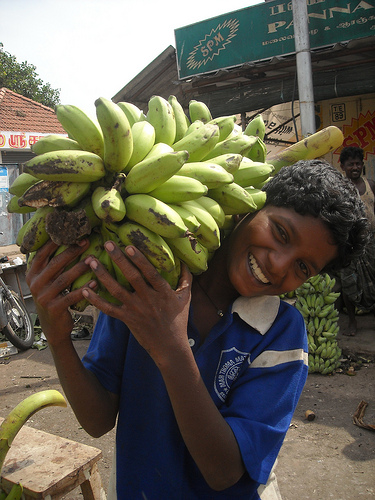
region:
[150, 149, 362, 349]
a boy is smiling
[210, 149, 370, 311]
boy has black curly hair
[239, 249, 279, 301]
teeth of boy are white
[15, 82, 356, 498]
boy carry a handles of bananas on right shoulder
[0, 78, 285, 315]
bananas are green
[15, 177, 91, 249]
two bananas are damaged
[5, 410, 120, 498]
a wood bench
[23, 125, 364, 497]
boy wears a blue short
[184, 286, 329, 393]
collar of blue short is white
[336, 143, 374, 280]
a woman wears a tank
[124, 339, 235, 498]
A boy in blue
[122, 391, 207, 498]
A boy in blue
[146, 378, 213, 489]
A boy in blue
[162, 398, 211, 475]
A boy in blue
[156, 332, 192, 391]
A boy in blue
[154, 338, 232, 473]
A boy in blue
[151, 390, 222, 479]
A boy in blue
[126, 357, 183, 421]
A boy in blue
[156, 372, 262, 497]
A boy in blue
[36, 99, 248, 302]
large bunch of green bananas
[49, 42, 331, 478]
boy holding bunch of bananas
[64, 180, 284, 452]
boy wearing blue sports shirt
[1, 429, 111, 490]
pale brown wooden stool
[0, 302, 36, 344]
tire of a motorbike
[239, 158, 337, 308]
man's smiling face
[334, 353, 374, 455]
trash on the ground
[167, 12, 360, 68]
green store sign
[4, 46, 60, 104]
dark green tree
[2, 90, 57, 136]
roof with red tiles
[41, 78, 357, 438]
boy carrying green bananas on his shoulder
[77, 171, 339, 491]
boy in a blue and white polo shirt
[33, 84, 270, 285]
large bunch of green bananas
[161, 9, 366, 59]
green building sign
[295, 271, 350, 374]
bunch of green bananas on the ground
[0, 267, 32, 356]
motorcycle tire in the background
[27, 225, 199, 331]
hands of a boy carrying bananas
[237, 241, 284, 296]
smile on a boy's face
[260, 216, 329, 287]
eyes of a boy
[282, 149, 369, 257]
black curly hair on a boy's head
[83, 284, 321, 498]
a blue and white shirt on a boy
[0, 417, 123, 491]
a wooden stool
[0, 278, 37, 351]
a wheel on a motorbike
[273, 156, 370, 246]
curly dark hair on a boy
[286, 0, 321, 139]
a metal pole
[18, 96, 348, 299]
a bunch of bananas on a boy's shoulder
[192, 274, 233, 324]
a necklace on a boy's neck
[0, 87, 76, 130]
a red clay tile roof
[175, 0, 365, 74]
a green sign behind a pole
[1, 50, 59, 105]
a tree behind a red roof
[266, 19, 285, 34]
a letter on a sign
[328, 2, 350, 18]
a letter on a sign